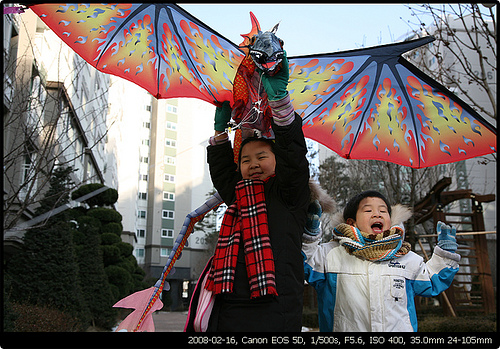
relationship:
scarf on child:
[199, 175, 284, 301] [204, 47, 311, 333]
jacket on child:
[189, 130, 314, 323] [204, 47, 311, 333]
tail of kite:
[143, 166, 218, 322] [20, 0, 497, 164]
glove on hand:
[212, 96, 232, 139] [211, 124, 223, 135]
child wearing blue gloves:
[306, 188, 468, 340] [436, 214, 457, 253]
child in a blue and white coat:
[306, 188, 468, 340] [306, 224, 470, 333]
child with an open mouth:
[306, 188, 468, 340] [367, 220, 383, 237]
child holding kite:
[204, 47, 311, 333] [20, 0, 497, 164]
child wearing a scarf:
[204, 47, 311, 333] [199, 175, 284, 301]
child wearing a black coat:
[204, 47, 311, 333] [189, 130, 314, 323]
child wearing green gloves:
[204, 47, 311, 333] [203, 53, 290, 128]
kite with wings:
[20, 0, 497, 164] [126, 16, 412, 168]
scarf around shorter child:
[326, 223, 415, 258] [306, 188, 468, 340]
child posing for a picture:
[204, 47, 311, 333] [184, 334, 499, 345]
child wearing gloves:
[204, 47, 311, 333] [203, 53, 290, 128]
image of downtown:
[114, 112, 423, 181] [442, 130, 499, 240]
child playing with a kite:
[204, 47, 311, 333] [20, 0, 497, 164]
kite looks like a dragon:
[20, 0, 497, 164] [208, 29, 288, 146]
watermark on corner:
[180, 333, 307, 347] [488, 334, 500, 348]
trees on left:
[5, 35, 60, 225] [12, 188, 26, 207]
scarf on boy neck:
[326, 223, 415, 258] [323, 237, 447, 300]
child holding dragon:
[204, 47, 311, 333] [208, 29, 288, 146]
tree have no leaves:
[403, 8, 498, 80] [439, 40, 454, 48]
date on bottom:
[183, 331, 238, 344] [137, 330, 151, 349]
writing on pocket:
[394, 276, 405, 292] [385, 267, 409, 303]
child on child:
[204, 47, 311, 333] [204, 112, 312, 332]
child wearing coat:
[204, 47, 311, 333] [204, 112, 307, 328]